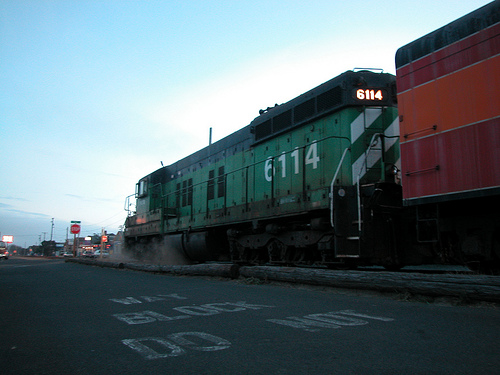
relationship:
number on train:
[346, 80, 390, 110] [140, 67, 392, 213]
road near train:
[41, 256, 207, 371] [140, 67, 392, 213]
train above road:
[140, 67, 392, 213] [41, 256, 207, 371]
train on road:
[140, 67, 392, 213] [41, 256, 207, 371]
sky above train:
[134, 5, 217, 54] [140, 67, 392, 213]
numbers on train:
[355, 85, 384, 103] [122, 0, 497, 271]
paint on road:
[110, 283, 393, 360] [41, 256, 207, 371]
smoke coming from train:
[91, 227, 191, 270] [140, 67, 392, 213]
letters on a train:
[105, 289, 397, 362] [140, 67, 392, 213]